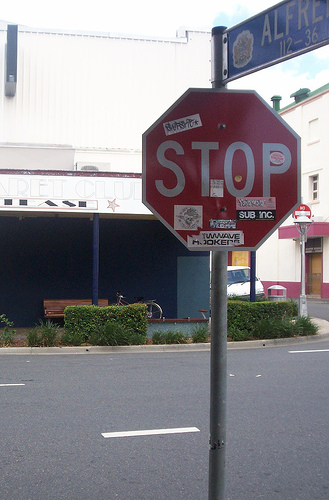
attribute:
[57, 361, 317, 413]
pavement — gray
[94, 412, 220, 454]
stripe — white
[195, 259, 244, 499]
pole — silver, grey, metal, gray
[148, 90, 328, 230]
sign — red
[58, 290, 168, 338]
bush — green, rectangular, trimmed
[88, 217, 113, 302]
pole — blue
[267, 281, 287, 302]
trash — cement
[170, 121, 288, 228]
stickers — strange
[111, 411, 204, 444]
line — white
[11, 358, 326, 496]
road — plain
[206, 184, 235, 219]
art — written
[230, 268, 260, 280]
window — in front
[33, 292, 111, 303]
bench — wooden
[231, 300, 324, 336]
hedge — green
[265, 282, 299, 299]
trashcan — grey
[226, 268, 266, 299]
van — white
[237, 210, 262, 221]
writing — white